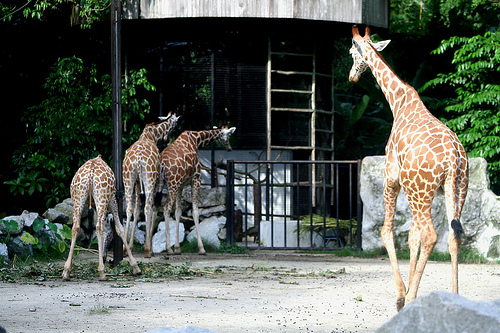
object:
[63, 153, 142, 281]
giraffe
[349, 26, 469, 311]
giraffe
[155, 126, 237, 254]
giraffe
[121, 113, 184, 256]
tall giraffe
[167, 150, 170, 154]
brown